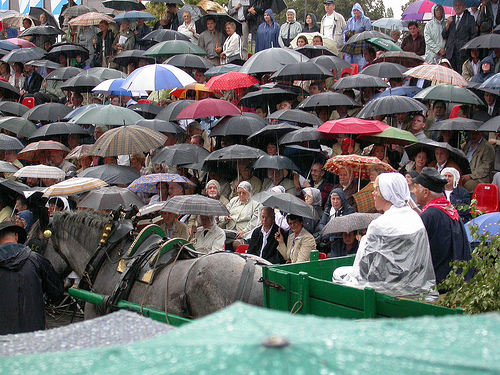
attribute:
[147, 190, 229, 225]
umbrella — black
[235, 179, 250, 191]
hat — rain, on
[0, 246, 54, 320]
jacket — black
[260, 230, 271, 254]
shirt — white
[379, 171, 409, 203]
hat on — white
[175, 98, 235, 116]
umbrella — membrane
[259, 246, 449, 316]
trailer — green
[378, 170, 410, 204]
cap — plastic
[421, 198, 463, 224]
scarf — man's, red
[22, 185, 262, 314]
horse — mostly gray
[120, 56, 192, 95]
umbrella — blue, white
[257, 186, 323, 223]
umbrella — open, black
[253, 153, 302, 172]
umbrella — black, open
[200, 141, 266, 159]
umbrella — open, black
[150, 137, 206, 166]
umbrella — black, open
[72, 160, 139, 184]
umbrella — open, black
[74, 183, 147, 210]
umbrella — black, open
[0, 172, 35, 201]
umbrella — open, black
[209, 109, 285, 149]
umbrella — open, black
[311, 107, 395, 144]
umbrella — red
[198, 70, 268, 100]
umbrella — red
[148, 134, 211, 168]
umbrella — black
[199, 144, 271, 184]
umbrella — black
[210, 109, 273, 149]
umbrella — black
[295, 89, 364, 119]
umbrella — black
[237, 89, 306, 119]
umbrella — black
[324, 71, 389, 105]
umbrella — black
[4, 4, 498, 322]
crowd — large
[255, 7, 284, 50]
jacket — blue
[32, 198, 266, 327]
horse — gray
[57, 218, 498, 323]
wagon — bright green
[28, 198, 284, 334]
horse — gray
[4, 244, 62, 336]
clothes — black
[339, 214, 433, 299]
clothes — old fashioned, plastic covered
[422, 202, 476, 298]
clothing — black, old fashioned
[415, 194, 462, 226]
bandana — red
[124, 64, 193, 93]
umbrella — blue, white, striped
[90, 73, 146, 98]
umbrella — striped, blue, white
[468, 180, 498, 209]
chair — red, plastic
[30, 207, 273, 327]
horse — grey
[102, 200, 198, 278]
saddle — leather, black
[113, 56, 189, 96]
umbrella — blue, white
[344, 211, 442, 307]
covering — white, plastic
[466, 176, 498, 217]
chair — red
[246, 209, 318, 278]
couple — elderly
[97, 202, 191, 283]
saddle — black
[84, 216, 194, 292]
embellishments — gold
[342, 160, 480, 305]
couple — elderly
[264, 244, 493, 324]
carriage — horse drawn